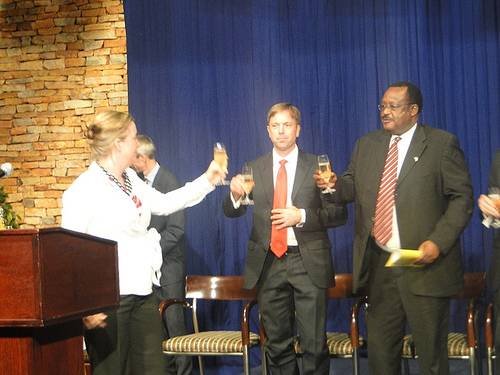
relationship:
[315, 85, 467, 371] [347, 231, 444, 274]
man holding book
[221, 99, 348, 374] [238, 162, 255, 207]
man holding glass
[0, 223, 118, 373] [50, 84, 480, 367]
podium for speakers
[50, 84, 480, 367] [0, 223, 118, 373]
speakers at podium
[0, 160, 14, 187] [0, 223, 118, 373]
microphone at podium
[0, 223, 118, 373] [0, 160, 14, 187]
podium has microphone